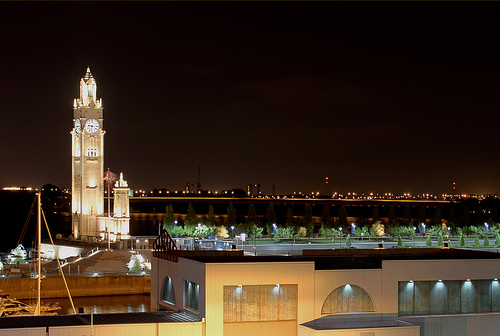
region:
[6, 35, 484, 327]
photograph taken of a city at night time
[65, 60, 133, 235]
large brick clock tower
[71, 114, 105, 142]
two white clocks with black hands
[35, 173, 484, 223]
lights of city in the distance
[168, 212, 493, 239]
row of green trees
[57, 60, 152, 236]
clock tower lit up with lights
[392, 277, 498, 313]
lights shining down on windows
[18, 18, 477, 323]
photo taken at night time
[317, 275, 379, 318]
arched window with a light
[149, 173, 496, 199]
many lights in the distance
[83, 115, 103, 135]
A large white clock on the clock tower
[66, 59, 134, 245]
A brightly lit stone clock tower in the distance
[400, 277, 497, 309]
Small blue white lights on the building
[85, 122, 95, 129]
The black hands of the white clock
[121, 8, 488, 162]
A deep black sky above the city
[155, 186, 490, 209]
A row of yellow lights in the distance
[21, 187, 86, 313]
A large white pole by the building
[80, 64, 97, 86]
A spire atop the clock tower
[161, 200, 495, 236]
A row of green trees by the clock tower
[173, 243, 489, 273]
The flat rooftop of the stone building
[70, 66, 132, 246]
tower is let up well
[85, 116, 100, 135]
clock tells the time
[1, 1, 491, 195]
very few clouds fill the sky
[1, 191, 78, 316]
boat sits in the canal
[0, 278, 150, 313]
canal has water in it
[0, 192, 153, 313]
canal has a boat in it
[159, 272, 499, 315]
windows are lit up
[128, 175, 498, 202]
skyline is lit up since the sun is not out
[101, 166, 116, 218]
flag flies on the pole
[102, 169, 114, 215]
flag flies on the building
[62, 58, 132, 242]
tall tan clock tower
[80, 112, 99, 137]
white clock face with black numbers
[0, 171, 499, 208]
series of yellow lights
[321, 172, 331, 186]
two small red lights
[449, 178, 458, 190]
two small red lights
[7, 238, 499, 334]
illuminated tan building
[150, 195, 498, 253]
row of partially lit green trees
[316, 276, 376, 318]
semi circle shaped window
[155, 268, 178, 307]
semi circle shaped window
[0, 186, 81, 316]
docked sail boat mast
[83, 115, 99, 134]
Front face of clock.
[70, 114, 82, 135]
Side face of clock.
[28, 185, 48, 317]
Sail boat's mast pole.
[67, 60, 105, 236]
clock tower with lights.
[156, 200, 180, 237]
Tree illuminated by light.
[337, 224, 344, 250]
Light pole near road.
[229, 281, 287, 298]
Lights on outside of building.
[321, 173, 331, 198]
Red lights in the distance.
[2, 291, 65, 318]
Boats on the water.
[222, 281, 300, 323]
Windows on a building.